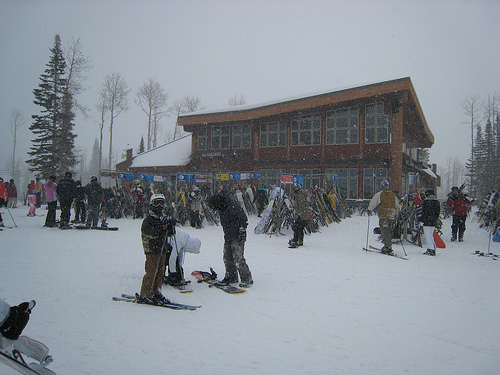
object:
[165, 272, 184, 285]
boot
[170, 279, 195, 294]
snowboard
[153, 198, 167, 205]
goggles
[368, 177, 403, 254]
person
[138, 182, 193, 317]
person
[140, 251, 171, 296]
pants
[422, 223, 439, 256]
pants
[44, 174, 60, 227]
jacket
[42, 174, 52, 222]
person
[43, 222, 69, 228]
snowboard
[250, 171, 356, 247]
pile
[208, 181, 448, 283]
people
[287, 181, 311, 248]
person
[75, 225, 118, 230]
snowboard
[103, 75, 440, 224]
ski lodge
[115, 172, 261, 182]
banners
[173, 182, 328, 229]
ski rack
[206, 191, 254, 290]
person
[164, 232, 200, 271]
jacket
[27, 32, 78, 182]
evergreen tree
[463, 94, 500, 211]
evergreen tree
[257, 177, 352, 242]
snowboards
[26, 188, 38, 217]
child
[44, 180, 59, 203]
jacket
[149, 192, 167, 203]
helmet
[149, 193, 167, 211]
head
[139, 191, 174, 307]
boy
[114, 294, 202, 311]
skis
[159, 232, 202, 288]
person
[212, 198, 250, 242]
jacket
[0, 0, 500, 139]
snowy sky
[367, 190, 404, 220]
jacket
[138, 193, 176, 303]
blue ski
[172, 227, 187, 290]
pole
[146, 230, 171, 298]
pole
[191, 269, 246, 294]
snowboard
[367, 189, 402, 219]
brown jacket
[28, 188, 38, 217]
person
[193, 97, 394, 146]
windows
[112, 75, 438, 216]
building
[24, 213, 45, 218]
snow gear